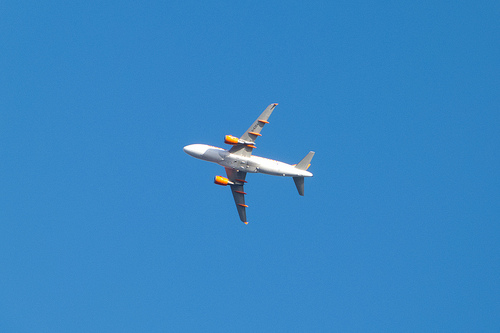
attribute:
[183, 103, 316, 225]
airplane — commercial, flying, white, orange, central, wheelless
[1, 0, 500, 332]
sky — blue, big, cloudless, bright, sunny, clear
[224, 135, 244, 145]
engine — orange, orage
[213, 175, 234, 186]
engine — orange, orage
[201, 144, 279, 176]
fuselage — white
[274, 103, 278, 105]
accent — orange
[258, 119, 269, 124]
accent — orange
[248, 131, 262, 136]
accent — orange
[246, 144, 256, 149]
accent — orange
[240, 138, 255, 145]
mount — gray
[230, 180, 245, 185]
mount — gray